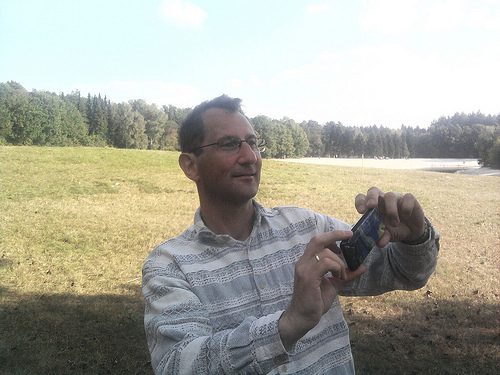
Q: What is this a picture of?
A: A man taking a picture.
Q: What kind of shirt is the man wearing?
A: A long sleeved shirt.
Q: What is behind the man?
A: Trees.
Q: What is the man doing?
A: Taking a photo.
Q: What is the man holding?
A: A phone.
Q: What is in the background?
A: Trees.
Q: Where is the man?
A: In a field.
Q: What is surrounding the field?
A: Trees.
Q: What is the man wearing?
A: A shirt.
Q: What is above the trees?
A: The sky.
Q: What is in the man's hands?
A: A phone.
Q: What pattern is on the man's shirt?
A: Stripes.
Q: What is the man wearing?
A: Glasses.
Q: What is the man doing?
A: Taking a picture.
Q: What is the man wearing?
A: A grey and white striped shirt.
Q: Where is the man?
A: In a field of brown grass.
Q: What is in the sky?
A: Clouds.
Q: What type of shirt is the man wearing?
A: Long sleeved button down shirt.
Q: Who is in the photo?
A: A man.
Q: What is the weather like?
A: Sunny.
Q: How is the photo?
A: Clear.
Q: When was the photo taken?
A: Daytime.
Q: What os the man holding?
A: A camera.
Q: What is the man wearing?
A: Glasses.